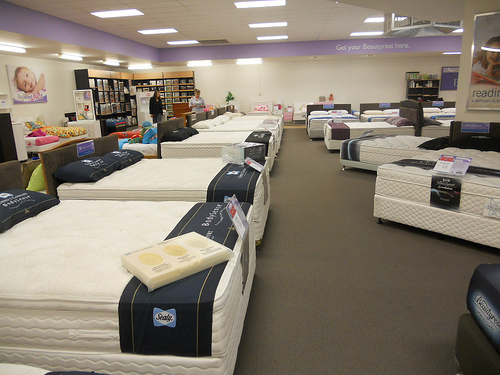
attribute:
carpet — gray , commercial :
[234, 128, 490, 373]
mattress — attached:
[0, 190, 255, 358]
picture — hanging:
[4, 62, 49, 104]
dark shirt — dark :
[147, 89, 167, 118]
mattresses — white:
[1, 190, 260, 373]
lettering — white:
[337, 40, 416, 50]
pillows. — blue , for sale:
[80, 144, 135, 174]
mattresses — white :
[132, 144, 230, 256]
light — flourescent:
[88, 2, 143, 28]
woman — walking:
[149, 90, 166, 123]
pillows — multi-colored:
[174, 124, 251, 182]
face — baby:
[21, 70, 38, 107]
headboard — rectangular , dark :
[59, 140, 142, 179]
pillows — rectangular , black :
[46, 144, 147, 185]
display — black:
[68, 69, 205, 123]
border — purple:
[326, 37, 451, 52]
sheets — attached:
[17, 112, 297, 360]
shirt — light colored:
[185, 93, 212, 112]